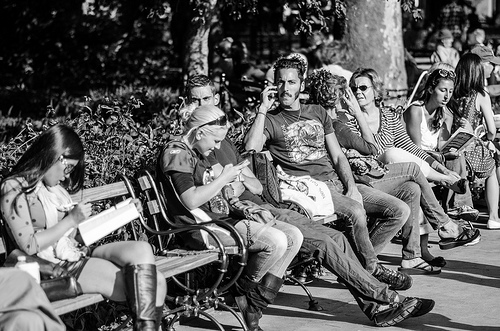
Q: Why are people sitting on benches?
A: To rest.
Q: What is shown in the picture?
A: A park area.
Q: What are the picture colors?
A: It's black and white.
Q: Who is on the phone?
A: The man with the side burns.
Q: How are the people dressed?
A: Light.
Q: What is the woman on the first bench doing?
A: Reading.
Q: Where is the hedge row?
A: Behind the benches.